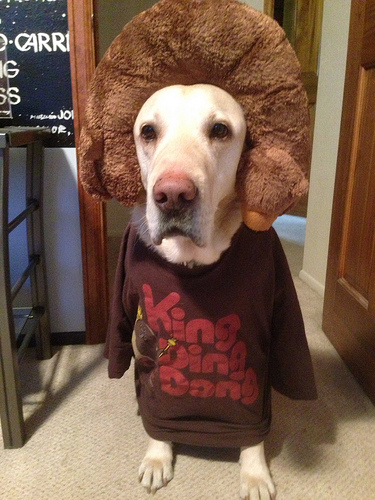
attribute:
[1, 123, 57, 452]
table — metal, brown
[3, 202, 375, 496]
carpet — white, tan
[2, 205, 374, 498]
floor — carpeted, beige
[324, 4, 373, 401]
door — wooden, interior, wood, brown, stained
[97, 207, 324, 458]
shirt — brown, cotton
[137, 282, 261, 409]
writing — red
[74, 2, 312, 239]
object — brown, fur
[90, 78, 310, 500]
dog — white, tan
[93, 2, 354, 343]
doorway — open, to room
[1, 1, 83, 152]
sign — blue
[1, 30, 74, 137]
writing — white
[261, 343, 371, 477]
shadow — dogs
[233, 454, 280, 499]
paws — white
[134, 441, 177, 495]
paws — white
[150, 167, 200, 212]
nose — pink, brown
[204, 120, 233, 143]
eyes — open, brown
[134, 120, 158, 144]
eyes — open, brown